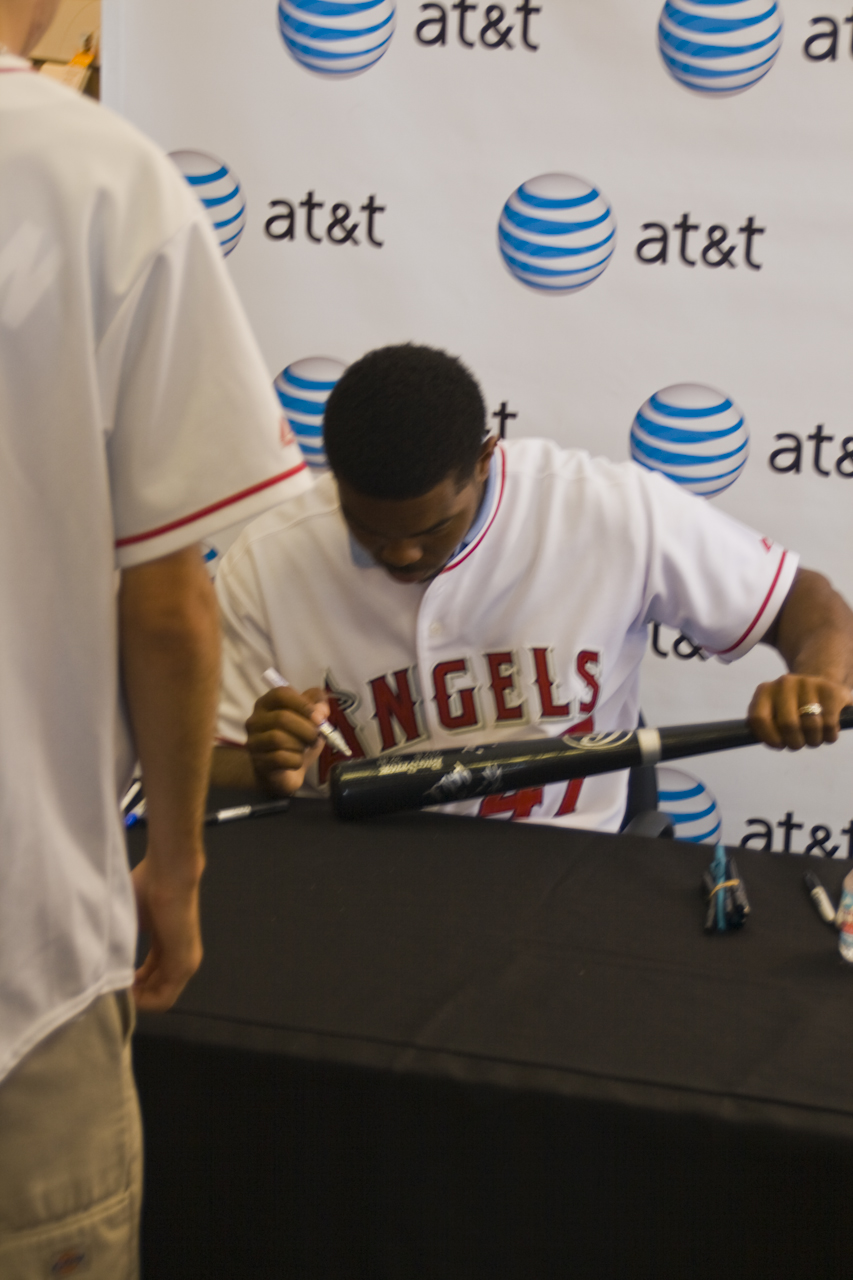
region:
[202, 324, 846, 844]
A player signing a baseball bat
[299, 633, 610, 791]
"ANGELS" written on shirt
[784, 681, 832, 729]
Ring around a finger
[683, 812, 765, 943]
A bunch of pens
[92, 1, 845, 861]
An "at&t" advertisement on wall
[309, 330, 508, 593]
Black hair on a man's head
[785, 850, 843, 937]
A black capped marker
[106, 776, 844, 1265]
Black cloth on a table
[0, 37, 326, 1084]
A white short sleeved shirt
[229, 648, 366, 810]
A white marker in a hand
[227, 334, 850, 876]
the man holding the bat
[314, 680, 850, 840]
the bat is black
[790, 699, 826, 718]
the ring on the finger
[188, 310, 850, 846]
the man signing the bat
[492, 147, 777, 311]
the logo on the wall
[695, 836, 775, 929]
the pens on the table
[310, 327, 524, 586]
the head of the man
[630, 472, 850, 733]
arm of the man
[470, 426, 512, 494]
ear of the man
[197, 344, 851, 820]
the man is signing a bat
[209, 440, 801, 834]
the jersey is red and white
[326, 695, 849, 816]
the bat is black and silver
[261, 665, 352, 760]
the pen is white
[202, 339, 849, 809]
the man is wearing a ring